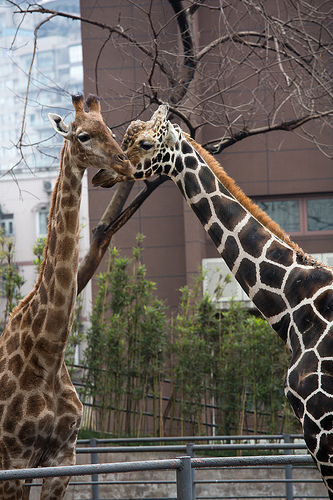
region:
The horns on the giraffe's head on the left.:
[65, 84, 99, 107]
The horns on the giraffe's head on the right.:
[148, 99, 169, 118]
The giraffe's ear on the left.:
[50, 102, 74, 141]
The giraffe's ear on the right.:
[161, 116, 180, 137]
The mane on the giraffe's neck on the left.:
[0, 136, 62, 320]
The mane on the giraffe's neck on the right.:
[181, 132, 327, 279]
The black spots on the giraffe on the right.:
[181, 159, 330, 499]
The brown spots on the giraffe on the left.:
[1, 150, 95, 496]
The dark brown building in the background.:
[79, 0, 332, 438]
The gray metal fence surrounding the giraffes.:
[3, 421, 329, 498]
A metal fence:
[155, 443, 199, 484]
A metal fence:
[149, 457, 176, 491]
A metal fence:
[137, 411, 170, 478]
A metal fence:
[145, 399, 210, 492]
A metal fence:
[172, 426, 201, 478]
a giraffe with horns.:
[46, 91, 139, 186]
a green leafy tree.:
[118, 256, 237, 436]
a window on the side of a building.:
[240, 193, 331, 231]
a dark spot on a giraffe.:
[207, 195, 245, 231]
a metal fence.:
[0, 429, 331, 497]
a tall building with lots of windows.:
[0, 0, 87, 175]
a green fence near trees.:
[61, 361, 302, 432]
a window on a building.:
[23, 186, 82, 246]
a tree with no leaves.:
[0, 0, 330, 296]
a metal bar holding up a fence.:
[281, 462, 294, 499]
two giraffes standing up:
[23, 80, 329, 396]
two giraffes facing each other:
[40, 86, 294, 304]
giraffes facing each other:
[19, 61, 303, 293]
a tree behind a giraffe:
[23, 63, 285, 344]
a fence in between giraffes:
[5, 308, 332, 498]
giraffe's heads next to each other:
[29, 62, 246, 220]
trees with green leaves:
[94, 265, 285, 425]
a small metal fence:
[72, 406, 321, 496]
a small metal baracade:
[109, 422, 281, 498]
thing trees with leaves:
[86, 251, 272, 424]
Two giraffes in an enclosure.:
[10, 81, 328, 490]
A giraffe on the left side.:
[9, 91, 135, 473]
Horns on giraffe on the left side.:
[63, 81, 106, 116]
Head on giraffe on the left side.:
[40, 87, 135, 189]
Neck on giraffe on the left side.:
[17, 143, 93, 331]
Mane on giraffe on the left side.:
[4, 137, 74, 336]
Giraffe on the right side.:
[100, 105, 332, 486]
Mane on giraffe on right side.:
[178, 123, 328, 286]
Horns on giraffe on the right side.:
[140, 97, 176, 131]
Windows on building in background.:
[246, 182, 332, 243]